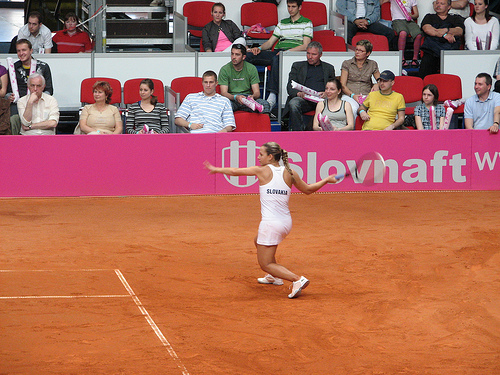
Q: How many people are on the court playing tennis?
A: One.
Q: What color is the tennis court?
A: Brown.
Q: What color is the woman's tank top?
A: White.